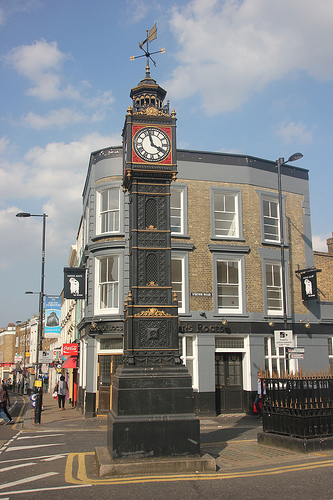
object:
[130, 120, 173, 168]
clock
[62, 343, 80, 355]
logo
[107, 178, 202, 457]
pillar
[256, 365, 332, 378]
tips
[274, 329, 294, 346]
sign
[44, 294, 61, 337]
sign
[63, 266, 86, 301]
sign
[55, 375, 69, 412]
person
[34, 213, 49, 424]
lightpost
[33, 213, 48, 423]
post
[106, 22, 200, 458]
tower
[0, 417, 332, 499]
streets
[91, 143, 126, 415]
building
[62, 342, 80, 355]
sign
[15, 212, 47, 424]
light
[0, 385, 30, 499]
street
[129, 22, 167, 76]
weathervane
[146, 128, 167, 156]
3:58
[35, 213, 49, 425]
pole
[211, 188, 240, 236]
window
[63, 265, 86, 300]
flag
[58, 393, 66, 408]
pants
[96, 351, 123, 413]
door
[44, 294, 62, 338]
flag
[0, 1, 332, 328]
sky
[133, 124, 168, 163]
face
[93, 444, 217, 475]
pedestal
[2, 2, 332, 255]
clouds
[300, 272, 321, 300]
banner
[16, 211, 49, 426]
street light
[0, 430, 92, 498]
paint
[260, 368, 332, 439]
fence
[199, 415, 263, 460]
shadow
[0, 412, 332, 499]
ground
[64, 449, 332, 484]
paint